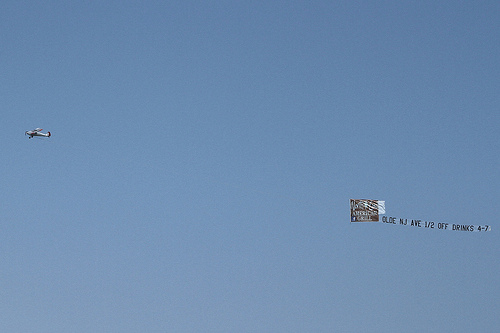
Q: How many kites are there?
A: One.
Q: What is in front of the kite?
A: A plane.